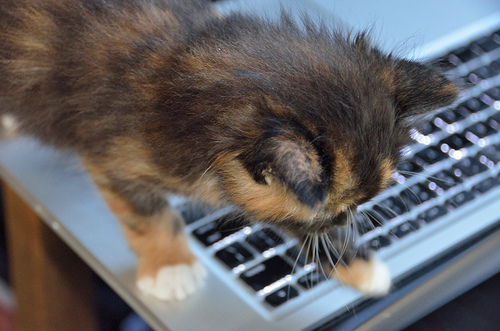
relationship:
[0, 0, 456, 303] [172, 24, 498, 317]
cat on keyboard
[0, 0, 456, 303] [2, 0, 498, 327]
cat on laptop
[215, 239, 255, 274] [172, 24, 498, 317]
key on keyboard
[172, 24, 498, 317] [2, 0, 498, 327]
keyboard on laptop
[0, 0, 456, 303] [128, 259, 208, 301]
cat has paw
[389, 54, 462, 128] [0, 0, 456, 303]
ear on cat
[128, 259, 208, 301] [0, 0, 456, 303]
paw on cat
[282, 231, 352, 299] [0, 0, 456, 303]
whiskers on cat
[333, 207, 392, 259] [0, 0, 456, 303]
eyelash on cat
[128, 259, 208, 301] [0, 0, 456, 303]
paw of cat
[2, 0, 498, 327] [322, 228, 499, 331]
laptop on desk